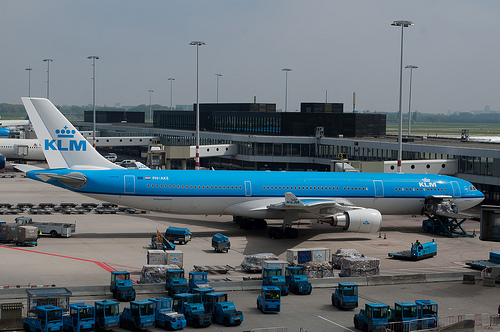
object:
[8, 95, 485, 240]
plane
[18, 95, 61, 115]
terminal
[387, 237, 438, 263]
cart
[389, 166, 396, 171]
window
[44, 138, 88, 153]
klm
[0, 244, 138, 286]
paint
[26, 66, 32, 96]
light post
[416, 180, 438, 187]
airline name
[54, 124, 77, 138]
crown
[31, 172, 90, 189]
wing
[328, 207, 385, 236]
engine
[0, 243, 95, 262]
line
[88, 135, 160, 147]
hallway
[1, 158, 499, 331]
airport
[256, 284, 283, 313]
transport car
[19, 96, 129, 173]
tail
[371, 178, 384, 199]
door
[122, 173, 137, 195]
door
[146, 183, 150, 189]
window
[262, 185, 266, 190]
window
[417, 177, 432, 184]
logo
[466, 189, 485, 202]
nose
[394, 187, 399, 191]
window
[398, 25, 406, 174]
pole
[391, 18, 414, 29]
lights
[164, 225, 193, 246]
cart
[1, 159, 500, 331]
tarmac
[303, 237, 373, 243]
shadow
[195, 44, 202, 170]
mast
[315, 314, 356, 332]
marking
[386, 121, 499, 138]
vegetation